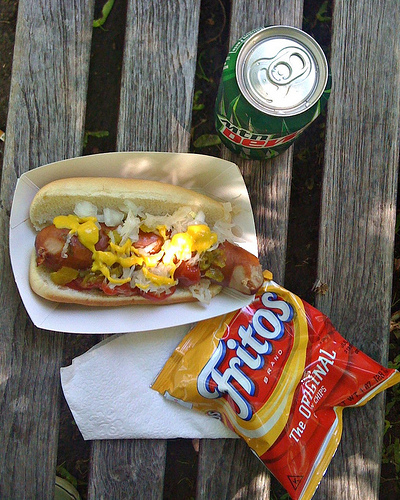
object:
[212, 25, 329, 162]
can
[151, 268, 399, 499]
bag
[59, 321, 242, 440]
napkin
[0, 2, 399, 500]
bench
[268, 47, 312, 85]
tab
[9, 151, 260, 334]
container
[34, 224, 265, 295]
hotdog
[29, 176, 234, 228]
bun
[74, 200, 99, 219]
onions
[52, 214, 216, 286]
mustard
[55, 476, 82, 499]
shoe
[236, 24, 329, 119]
top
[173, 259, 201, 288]
ketchup